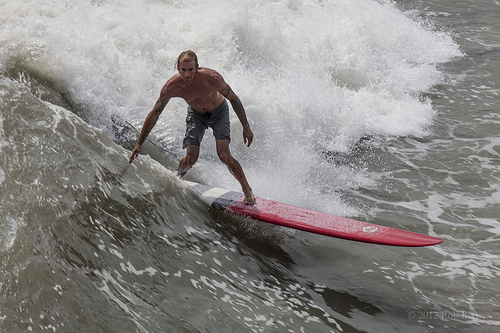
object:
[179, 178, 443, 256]
surfboard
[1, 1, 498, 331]
water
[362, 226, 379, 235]
logo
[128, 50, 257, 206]
man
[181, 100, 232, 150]
shorts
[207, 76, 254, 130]
arm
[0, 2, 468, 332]
wave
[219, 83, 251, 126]
tattoos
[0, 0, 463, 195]
foam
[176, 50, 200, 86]
head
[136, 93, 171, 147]
arm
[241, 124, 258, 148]
hand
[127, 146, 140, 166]
hand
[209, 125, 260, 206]
leg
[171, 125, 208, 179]
leg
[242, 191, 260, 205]
feet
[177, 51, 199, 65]
hair